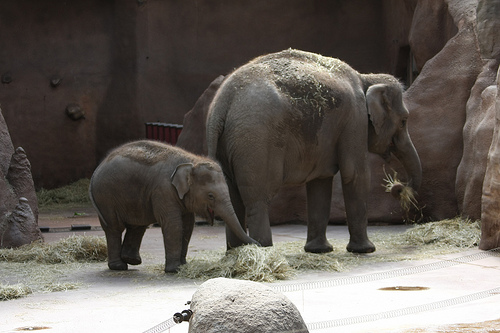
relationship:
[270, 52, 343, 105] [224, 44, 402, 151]
grass on elephant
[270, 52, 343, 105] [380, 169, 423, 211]
grass on trunk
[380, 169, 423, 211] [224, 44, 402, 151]
trunk of elephant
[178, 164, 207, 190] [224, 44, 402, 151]
ear of elephant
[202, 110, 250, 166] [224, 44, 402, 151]
tail of elephant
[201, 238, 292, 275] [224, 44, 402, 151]
food in elephant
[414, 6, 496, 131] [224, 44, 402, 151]
rocks near elephant